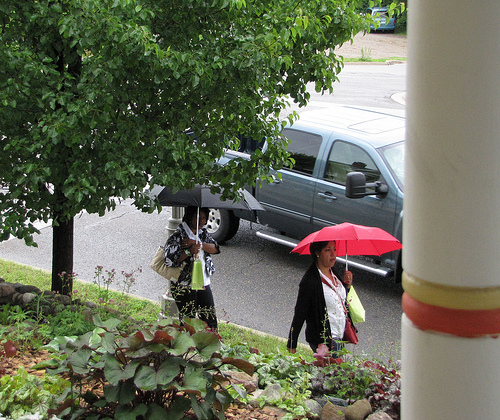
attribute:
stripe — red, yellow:
[398, 264, 498, 346]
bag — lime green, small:
[346, 285, 368, 323]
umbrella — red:
[286, 220, 402, 272]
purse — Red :
[319, 273, 359, 344]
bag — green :
[333, 275, 375, 328]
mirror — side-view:
[341, 167, 385, 203]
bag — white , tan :
[148, 252, 187, 283]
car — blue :
[235, 82, 417, 240]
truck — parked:
[180, 97, 421, 289]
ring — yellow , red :
[389, 257, 499, 347]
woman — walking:
[248, 245, 421, 387]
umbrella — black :
[153, 174, 262, 255]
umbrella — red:
[277, 218, 413, 257]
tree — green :
[2, 6, 373, 306]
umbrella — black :
[146, 176, 260, 215]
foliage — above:
[30, 307, 274, 408]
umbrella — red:
[294, 217, 403, 262]